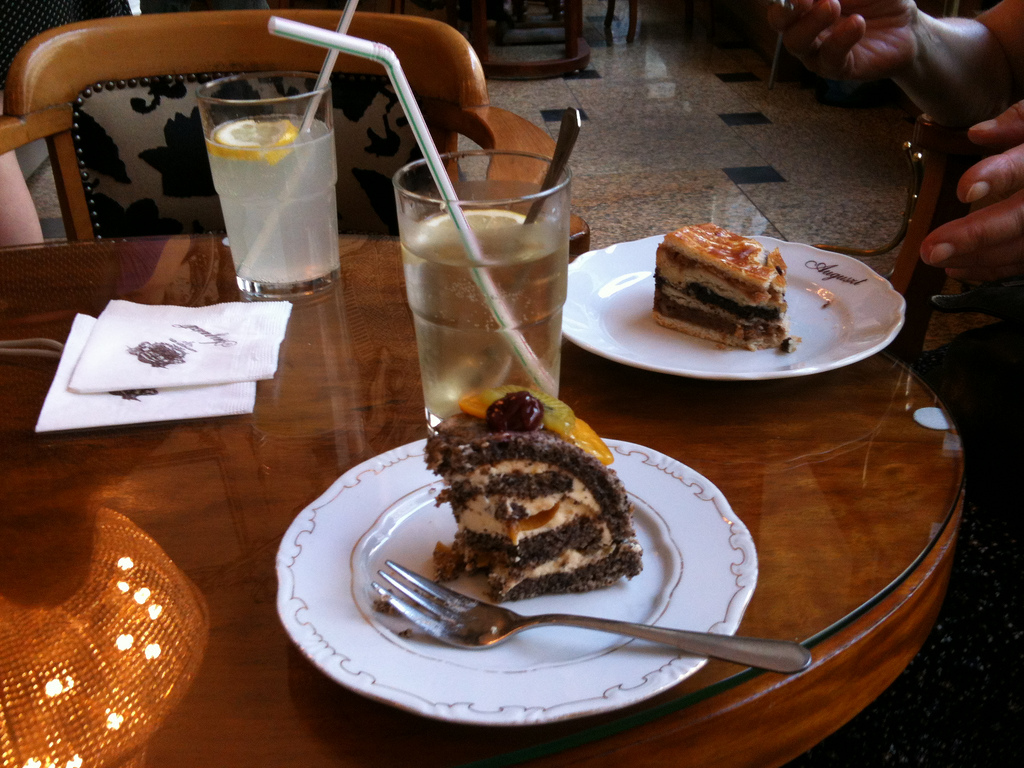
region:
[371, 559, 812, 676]
A silver fork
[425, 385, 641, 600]
Cake with cherry on top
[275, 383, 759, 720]
Cake on a white plate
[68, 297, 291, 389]
White and brown napkin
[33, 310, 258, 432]
White and brown napkin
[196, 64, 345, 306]
Glass with a lemon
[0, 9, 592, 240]
An old wooden chair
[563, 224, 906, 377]
Cake on a white plate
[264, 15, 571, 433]
White and green straw in a glass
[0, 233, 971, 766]
Old wooden table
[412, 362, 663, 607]
Cake on a plate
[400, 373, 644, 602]
Cake is on a plate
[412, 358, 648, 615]
Slice of cake on a plate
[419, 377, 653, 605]
Slice of cake is on a plate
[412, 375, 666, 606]
Cake on a white plate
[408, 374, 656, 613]
Cake is on a white plate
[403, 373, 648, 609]
Slice of cake on a white plate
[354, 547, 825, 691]
Fork is on a white plate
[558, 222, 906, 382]
plate with layered cake slice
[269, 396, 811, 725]
plate with fork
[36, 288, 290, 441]
white napkins with detailing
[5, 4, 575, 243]
chair with rounded back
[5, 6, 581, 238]
chair with patterned back cushion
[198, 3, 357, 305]
glass of lemonade with straw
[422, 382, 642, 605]
partially eaten piece of dessert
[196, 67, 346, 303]
glass with lemon inside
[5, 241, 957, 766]
reflection of lamp in tabletop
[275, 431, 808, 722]
a silver fork propped on a white plate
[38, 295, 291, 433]
a paper napkin on top of another paper napkin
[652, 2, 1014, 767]
a person sitting in front of a piece of cake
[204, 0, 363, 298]
a lemonade with a lemon slice in it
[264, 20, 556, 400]
a white and green straw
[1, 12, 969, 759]
a chair sitting in front of an oval table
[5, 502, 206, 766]
a small wicker lamp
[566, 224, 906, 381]
a white plate with black writing on it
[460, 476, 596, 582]
food on the plate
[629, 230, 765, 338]
food on the plate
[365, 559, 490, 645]
fork on the plate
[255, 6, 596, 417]
a straw in a glass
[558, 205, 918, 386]
a pastry on a dish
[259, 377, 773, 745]
a pastry on a dish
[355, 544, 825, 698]
a fork on a dish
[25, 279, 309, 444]
two white napkins on a table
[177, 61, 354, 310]
a glass of lemonade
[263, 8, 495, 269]
the straw is curved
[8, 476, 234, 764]
teh reflection on a table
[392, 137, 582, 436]
glass of water on table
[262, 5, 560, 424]
straw in glass of water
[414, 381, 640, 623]
slice of cake on plate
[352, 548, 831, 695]
fork by cake on plate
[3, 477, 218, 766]
reflection of lamp in table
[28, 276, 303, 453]
stack of napkins on table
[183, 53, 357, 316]
glass of lemonade on table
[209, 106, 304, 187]
slice of lemon in glass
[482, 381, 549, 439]
piece of fruit on cake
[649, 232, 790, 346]
a piece of cake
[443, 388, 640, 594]
a piece of cake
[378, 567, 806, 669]
the fork is silver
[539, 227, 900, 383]
the plate is white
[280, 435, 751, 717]
the plate is white